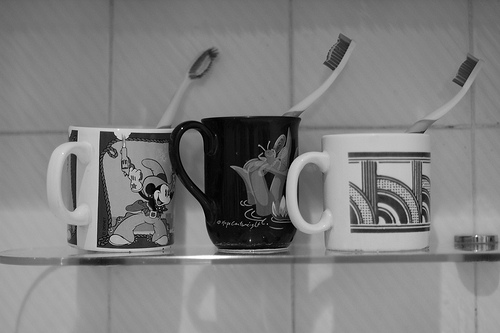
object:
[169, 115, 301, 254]
cup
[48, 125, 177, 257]
cup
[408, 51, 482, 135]
toothbrush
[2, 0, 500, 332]
wall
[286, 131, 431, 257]
cups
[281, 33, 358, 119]
toothbrushes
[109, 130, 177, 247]
mickey mouse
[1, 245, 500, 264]
shelf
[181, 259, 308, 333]
shadow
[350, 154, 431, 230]
image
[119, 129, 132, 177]
gun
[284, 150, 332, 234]
handle